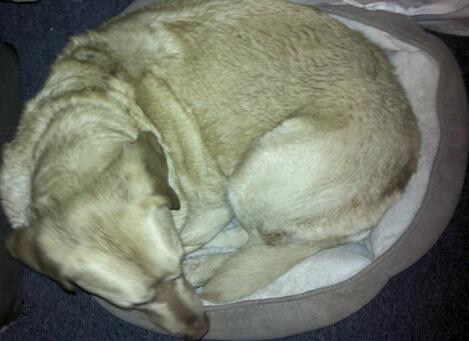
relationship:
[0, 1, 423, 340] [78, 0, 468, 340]
dog in a bed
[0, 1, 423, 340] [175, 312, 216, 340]
dog has a nose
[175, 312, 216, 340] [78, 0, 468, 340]
nose over edge of bed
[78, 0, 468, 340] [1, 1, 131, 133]
bed on carpet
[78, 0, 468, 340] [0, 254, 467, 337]
bed on carpet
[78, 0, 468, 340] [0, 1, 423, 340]
bed for a dog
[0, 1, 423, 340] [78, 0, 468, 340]
dog laying on bed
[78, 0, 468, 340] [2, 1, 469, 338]
bed on floor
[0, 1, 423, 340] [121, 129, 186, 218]
dog has an ear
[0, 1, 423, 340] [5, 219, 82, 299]
dog has an ear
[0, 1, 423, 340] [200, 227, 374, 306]
dog has a tail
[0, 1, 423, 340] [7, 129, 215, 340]
dog has a head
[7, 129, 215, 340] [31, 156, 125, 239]
head has a top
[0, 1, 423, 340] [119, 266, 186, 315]
dog has eyelids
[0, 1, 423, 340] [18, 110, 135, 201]
dog has a neck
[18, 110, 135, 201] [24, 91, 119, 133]
neck has a nape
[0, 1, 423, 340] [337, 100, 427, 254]
dog has a butt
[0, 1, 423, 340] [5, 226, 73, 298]
dog has ear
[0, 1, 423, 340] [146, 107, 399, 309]
dog has legs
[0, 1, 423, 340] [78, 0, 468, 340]
dog on bed